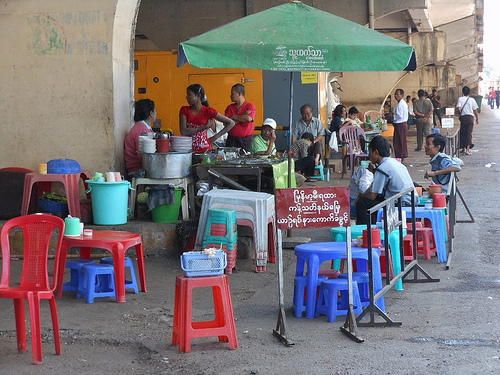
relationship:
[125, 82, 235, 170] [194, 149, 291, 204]
women behind table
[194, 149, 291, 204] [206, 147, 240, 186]
table has pot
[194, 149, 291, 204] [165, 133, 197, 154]
table has dishes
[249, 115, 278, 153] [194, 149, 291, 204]
man behind table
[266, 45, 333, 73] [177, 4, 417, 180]
writing on umbrella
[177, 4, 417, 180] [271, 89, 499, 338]
umbrella on sidewalk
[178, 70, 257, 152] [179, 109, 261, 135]
woman and man wearing red shirts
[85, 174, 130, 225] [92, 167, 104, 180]
bucket has rags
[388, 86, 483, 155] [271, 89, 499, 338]
people on sidewalk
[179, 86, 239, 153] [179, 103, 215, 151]
woman in red shirts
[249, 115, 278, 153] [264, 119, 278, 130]
man wears cap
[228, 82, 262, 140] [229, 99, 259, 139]
man in shirt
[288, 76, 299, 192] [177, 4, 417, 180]
pole holds umbrella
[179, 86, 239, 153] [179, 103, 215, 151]
woman has red shirts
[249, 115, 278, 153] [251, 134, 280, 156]
man wears shirt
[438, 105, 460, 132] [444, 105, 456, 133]
post holds signs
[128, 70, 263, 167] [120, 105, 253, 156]
woman and man in red shirts